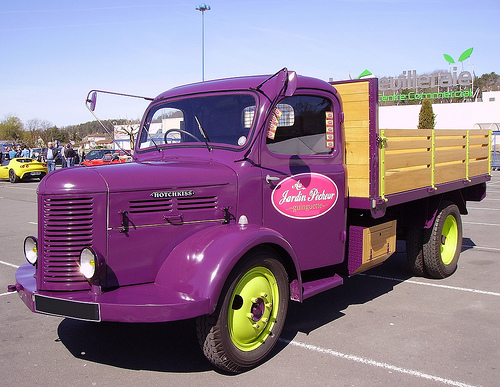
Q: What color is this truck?
A: Purple.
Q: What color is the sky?
A: Blue.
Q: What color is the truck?
A: Purple.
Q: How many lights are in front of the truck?
A: Two.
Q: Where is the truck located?
A: Parking lot.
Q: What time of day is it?
A: Noon.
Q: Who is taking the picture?
A: Passenger.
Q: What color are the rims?
A: Green.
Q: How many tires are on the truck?
A: Six.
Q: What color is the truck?
A: Purple.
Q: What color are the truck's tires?
A: Black.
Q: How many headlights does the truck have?
A: Two.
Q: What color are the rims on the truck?
A: Green.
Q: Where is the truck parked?
A: In a parking lot.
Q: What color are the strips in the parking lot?
A: White.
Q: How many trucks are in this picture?
A: One.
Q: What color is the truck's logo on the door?
A: Pink.